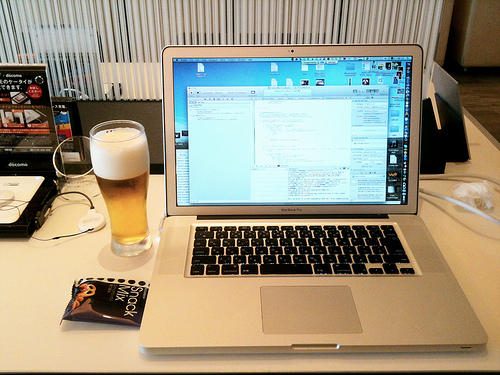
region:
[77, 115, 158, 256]
glass of beer next to the computer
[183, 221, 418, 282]
keyboard of the computer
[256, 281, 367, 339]
track pad of the computer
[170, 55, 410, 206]
screen of the computer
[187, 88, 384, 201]
window open on the computer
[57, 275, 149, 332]
snack next to the computer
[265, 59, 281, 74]
icon on the desktop of the computer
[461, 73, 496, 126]
floor in the computer room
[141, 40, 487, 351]
laptop computer that folds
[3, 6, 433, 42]
shutters in the computer's room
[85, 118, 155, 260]
Glass of foamy beer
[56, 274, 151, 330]
Bag of snack mix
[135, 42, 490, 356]
Silver laptop computer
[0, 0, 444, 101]
Hanging vertical blinds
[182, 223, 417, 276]
Black keyboard on a laptop computer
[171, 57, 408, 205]
Laptop computer screen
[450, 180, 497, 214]
Crumbled up piece of tissue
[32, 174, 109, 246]
Several computer cords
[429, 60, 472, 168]
The backside of a computer screen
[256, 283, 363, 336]
Touch pad on a laptop computer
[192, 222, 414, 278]
a black keyboard on a laptop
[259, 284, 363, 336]
a square laptop touchpad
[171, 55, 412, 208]
the lit up screen on a laptop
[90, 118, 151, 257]
a glass of beer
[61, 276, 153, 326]
a closed bag of snack mix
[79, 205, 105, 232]
a round white disc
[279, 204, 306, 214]
the brand logo of the laptop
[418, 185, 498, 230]
a white cord beside a laptop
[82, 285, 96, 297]
an image of a pretzel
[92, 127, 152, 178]
foam on a glass of beer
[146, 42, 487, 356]
a laptop computer that is turned on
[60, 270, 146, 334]
a small snack mix bag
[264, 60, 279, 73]
an icon on the computer's desktop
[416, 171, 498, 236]
a white power cable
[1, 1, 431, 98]
a white vertical curtain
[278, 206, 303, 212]
black letters that say mac book pro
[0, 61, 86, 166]
two magazines near laptop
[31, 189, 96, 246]
two black wires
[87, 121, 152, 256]
a glass of beer on the desk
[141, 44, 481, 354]
the laptop is open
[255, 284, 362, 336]
touch pad is gray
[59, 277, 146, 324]
a black bag of snacks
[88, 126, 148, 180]
white fizz on top of the beer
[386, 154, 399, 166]
a file on the desktop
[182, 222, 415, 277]
the computer keys are black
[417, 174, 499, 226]
a white power cord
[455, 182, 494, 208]
a used tissue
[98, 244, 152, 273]
beer glass shadow on the desk